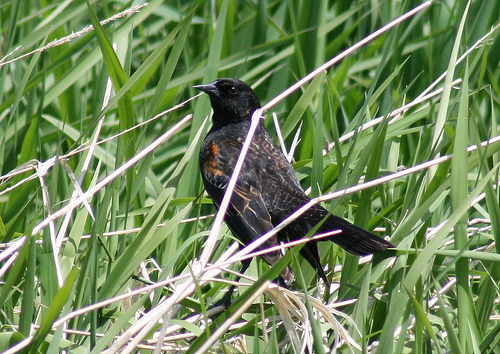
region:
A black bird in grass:
[163, 60, 410, 326]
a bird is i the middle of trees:
[156, 54, 331, 302]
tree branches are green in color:
[313, 26, 481, 150]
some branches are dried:
[170, 216, 285, 336]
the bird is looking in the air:
[195, 48, 336, 258]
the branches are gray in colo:
[157, 233, 272, 349]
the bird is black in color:
[187, 73, 318, 256]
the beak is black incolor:
[187, 77, 214, 100]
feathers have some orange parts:
[197, 140, 257, 195]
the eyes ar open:
[217, 73, 252, 108]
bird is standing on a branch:
[196, 164, 305, 304]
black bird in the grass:
[181, 66, 396, 280]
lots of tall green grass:
[45, 30, 187, 250]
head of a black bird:
[189, 70, 272, 115]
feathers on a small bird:
[210, 138, 362, 267]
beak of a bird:
[188, 73, 220, 100]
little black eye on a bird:
[228, 85, 240, 92]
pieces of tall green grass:
[37, 17, 157, 261]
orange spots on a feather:
[201, 136, 309, 207]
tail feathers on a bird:
[292, 164, 380, 269]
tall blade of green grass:
[453, 59, 472, 341]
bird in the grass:
[162, 67, 435, 307]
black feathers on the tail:
[315, 205, 401, 265]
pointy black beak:
[185, 80, 212, 95]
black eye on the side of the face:
[226, 81, 231, 91]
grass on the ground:
[0, 0, 496, 347]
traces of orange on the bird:
[206, 143, 228, 180]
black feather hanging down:
[280, 223, 340, 280]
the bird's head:
[188, 74, 258, 116]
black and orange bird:
[176, 65, 401, 291]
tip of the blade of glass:
[198, 112, 213, 126]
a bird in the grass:
[97, 33, 492, 323]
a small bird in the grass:
[166, 50, 496, 311]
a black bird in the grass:
[169, 68, 474, 338]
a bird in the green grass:
[192, 73, 392, 343]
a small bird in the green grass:
[160, 54, 490, 334]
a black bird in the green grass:
[175, 78, 342, 272]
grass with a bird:
[112, 43, 476, 351]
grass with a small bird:
[126, 52, 474, 286]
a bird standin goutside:
[107, 51, 479, 339]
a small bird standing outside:
[119, 41, 442, 351]